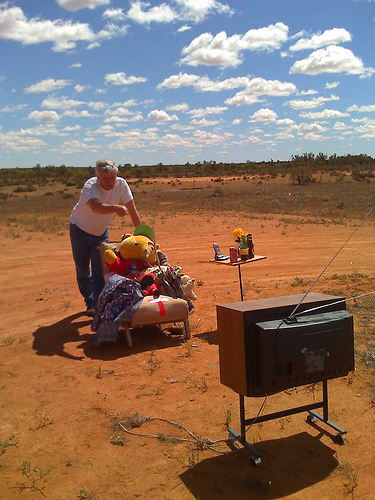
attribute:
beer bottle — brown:
[245, 230, 255, 259]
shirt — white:
[66, 176, 135, 237]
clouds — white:
[289, 46, 372, 80]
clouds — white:
[165, 69, 297, 111]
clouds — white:
[167, 23, 286, 69]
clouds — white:
[263, 117, 363, 148]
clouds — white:
[28, 105, 175, 153]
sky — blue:
[0, 0, 373, 160]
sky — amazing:
[1, 29, 374, 177]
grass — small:
[340, 465, 366, 490]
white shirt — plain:
[70, 174, 135, 231]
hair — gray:
[94, 160, 119, 175]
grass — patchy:
[292, 263, 373, 412]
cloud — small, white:
[99, 62, 138, 98]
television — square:
[219, 281, 344, 403]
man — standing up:
[68, 154, 143, 316]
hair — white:
[94, 157, 120, 173]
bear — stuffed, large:
[104, 231, 159, 278]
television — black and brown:
[215, 291, 356, 395]